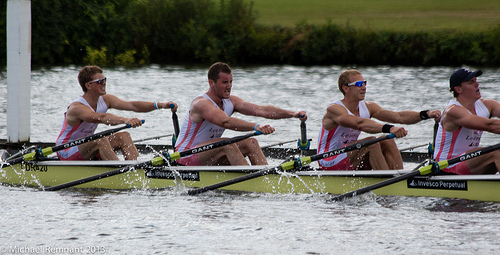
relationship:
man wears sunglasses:
[318, 69, 440, 177] [346, 79, 367, 86]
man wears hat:
[432, 67, 499, 174] [444, 63, 484, 88]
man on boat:
[55, 64, 179, 160] [2, 138, 499, 202]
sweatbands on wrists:
[378, 116, 398, 134] [340, 75, 430, 149]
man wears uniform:
[171, 62, 308, 167] [175, 95, 234, 164]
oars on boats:
[19, 95, 495, 210] [10, 138, 492, 210]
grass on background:
[292, 1, 384, 31] [4, 1, 498, 27]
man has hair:
[51, 74, 148, 154] [72, 60, 105, 84]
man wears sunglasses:
[55, 64, 179, 160] [86, 74, 109, 86]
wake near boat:
[1, 181, 379, 211] [2, 138, 499, 202]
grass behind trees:
[213, 1, 499, 34] [31, 0, 258, 65]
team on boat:
[57, 61, 499, 190] [2, 138, 499, 202]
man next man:
[432, 67, 499, 174] [316, 69, 442, 171]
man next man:
[316, 69, 442, 171] [173, 61, 305, 164]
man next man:
[173, 61, 305, 164] [55, 64, 179, 160]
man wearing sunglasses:
[55, 64, 179, 160] [86, 77, 108, 86]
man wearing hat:
[430, 67, 499, 175] [448, 65, 472, 85]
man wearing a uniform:
[55, 64, 179, 160] [54, 96, 111, 162]